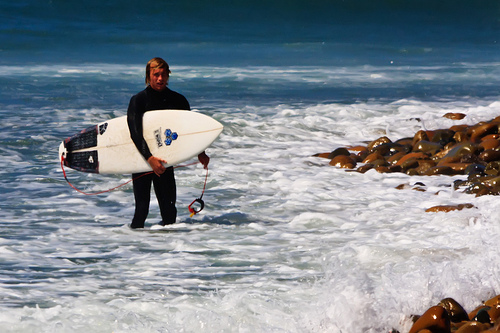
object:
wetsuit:
[126, 86, 196, 226]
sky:
[3, 0, 496, 42]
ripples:
[239, 273, 266, 283]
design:
[164, 129, 179, 146]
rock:
[438, 146, 485, 168]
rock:
[414, 139, 443, 152]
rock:
[406, 159, 433, 176]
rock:
[367, 135, 393, 152]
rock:
[329, 153, 357, 169]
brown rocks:
[329, 154, 357, 168]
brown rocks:
[410, 307, 452, 333]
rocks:
[480, 134, 499, 150]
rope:
[60, 154, 154, 195]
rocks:
[449, 125, 469, 143]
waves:
[3, 92, 498, 327]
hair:
[138, 57, 177, 86]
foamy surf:
[233, 99, 347, 140]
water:
[0, 0, 499, 332]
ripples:
[470, 227, 488, 243]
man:
[62, 50, 234, 217]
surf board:
[27, 112, 214, 180]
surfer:
[127, 57, 212, 229]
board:
[58, 110, 225, 176]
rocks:
[436, 297, 471, 322]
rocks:
[425, 203, 474, 213]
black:
[134, 95, 181, 108]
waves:
[364, 72, 389, 84]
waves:
[241, 62, 301, 80]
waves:
[26, 60, 86, 75]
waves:
[169, 63, 192, 79]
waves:
[459, 62, 494, 84]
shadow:
[179, 212, 270, 226]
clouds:
[104, 14, 202, 38]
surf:
[251, 148, 484, 331]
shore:
[314, 88, 498, 201]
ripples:
[9, 302, 60, 323]